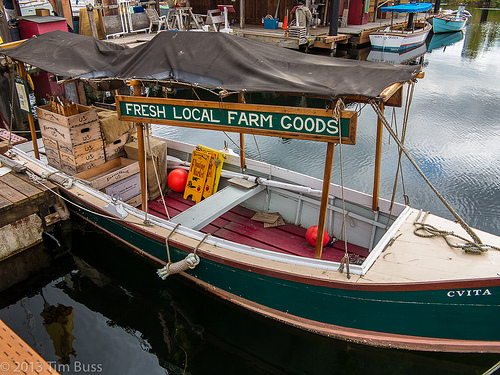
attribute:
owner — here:
[1, 355, 97, 372]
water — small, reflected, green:
[418, 109, 457, 131]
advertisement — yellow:
[118, 91, 354, 146]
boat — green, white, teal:
[220, 54, 319, 302]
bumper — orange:
[172, 173, 193, 181]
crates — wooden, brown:
[57, 122, 105, 147]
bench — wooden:
[207, 212, 227, 225]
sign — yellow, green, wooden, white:
[312, 111, 332, 135]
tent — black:
[163, 28, 213, 47]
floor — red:
[220, 224, 262, 229]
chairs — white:
[27, 5, 60, 21]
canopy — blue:
[71, 57, 113, 84]